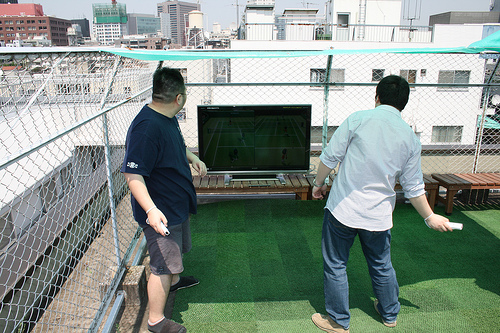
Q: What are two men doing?
A: Playing a video game.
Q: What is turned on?
A: TV screen.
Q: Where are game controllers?
A: In men's hands.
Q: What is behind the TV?
A: A fence.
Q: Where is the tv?
A: On bench.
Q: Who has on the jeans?
A: Man on right.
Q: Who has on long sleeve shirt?
A: Man on right.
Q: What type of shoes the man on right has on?
A: Boots.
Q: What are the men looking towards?
A: T.v.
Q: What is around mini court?
A: A fence.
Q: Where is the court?
A: On top of building.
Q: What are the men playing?
A: A tennis video game.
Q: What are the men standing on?
A: Astroturf.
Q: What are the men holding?
A: Wii Remotes.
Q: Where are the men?
A: On the roof.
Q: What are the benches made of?
A: Wood.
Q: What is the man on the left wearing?
A: A shirt and shorts.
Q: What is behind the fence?
A: Other buildings.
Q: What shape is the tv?
A: Rectangular.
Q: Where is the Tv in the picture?
A: Next to fence.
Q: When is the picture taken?
A: Daytime.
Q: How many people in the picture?
A: Two.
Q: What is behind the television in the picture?
A: Fence.